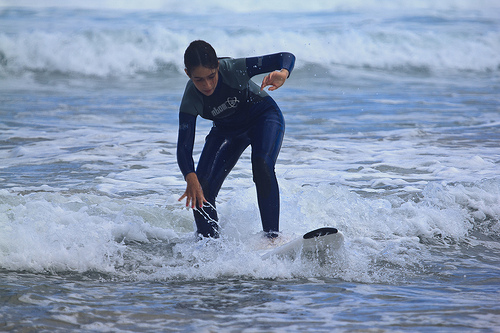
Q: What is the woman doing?
A: Surfing.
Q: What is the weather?
A: Pleasant.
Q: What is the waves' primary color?
A: Blue.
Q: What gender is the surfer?
A: Female.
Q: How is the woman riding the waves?
A: Surfboard.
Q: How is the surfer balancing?
A: Holding out arms.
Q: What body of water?
A: Ocean.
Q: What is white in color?
A: The surfboard is white.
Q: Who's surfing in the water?
A: A woman.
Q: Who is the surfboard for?
A: The surfboard is for a woman.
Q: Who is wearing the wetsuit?
A: The woman is wearing the wetsuit.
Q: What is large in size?
A: The body of water.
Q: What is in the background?
A: Waves are in the background.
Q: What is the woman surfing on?
A: The woman is surfing on small waves.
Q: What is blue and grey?
A: The wetsuit is blue and grey.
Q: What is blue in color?
A: The waters are blue.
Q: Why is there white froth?
A: There is white froth from the waves crashing.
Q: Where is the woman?
A: On the surfboard.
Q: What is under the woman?
A: A surfboard.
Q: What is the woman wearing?
A: A wetsuit.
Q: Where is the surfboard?
A: In the water.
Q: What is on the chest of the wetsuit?
A: Writing.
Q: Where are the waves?
A: Behind the woman.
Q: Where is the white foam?
A: On the waves.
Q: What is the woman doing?
A: Surfing.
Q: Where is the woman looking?
A: Downwards.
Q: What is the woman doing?
A: Surfing.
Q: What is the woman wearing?
A: Wetsuit.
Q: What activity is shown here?
A: Surfing.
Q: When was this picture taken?
A: Daytime.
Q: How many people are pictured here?
A: One.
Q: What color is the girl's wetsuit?
A: Blue.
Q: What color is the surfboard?
A: White.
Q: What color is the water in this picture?
A: Blue.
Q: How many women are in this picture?
A: One.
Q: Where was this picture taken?
A: The ocean.